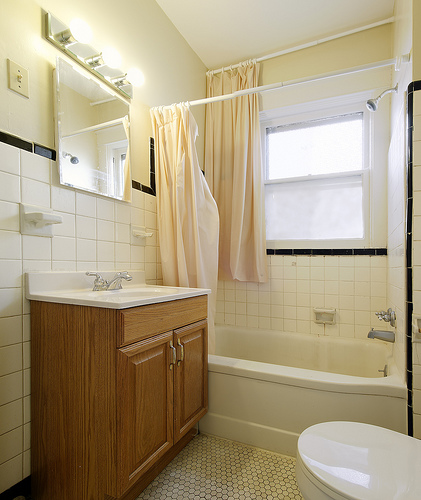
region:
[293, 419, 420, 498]
toilet with the seat and lid down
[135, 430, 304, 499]
hexagonal tile floor pattern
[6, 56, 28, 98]
light switch in the on position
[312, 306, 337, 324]
soap dish in the wall of the shower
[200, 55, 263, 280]
peach colored curtain on the higher rod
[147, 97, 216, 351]
peach shower curtain on the lower pole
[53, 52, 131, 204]
mirror reflecting the shower head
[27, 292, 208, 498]
brown cabinets made out of wood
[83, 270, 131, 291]
silver metal sink faucet with two handles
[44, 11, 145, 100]
three lights in a row above the mirror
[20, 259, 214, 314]
sink in a bathroom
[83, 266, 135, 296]
faucet on a sink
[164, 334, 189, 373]
handles on vanity doors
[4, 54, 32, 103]
electrical switch on a wall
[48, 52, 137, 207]
mirror in a bathroom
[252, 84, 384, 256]
window on a wall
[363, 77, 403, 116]
shower head in a bathroom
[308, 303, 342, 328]
soap dish in a shower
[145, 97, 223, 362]
shower curtain on a rod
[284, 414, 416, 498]
white toilet in a bathroom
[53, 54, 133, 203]
Wall mounted mirror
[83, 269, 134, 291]
Silver double handle faucet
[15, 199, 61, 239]
White soap dish on wall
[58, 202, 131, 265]
White tiles on wall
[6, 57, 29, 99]
Single white light switch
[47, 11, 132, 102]
Silver wall mouted light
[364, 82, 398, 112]
Silver shower head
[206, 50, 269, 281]
Peach window curtain with white rod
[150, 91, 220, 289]
Peach shower curtain with white rod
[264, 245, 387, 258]
Black tile boarder under window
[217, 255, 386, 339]
White tiles on bathroom wall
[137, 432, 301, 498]
Hexagonal small tiles on bathroom floor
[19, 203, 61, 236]
Soap holder among tiles on wall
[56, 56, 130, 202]
Medicine cabinet mirror in bathroom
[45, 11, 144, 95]
Three light-bulb strip with mirror back in bathroom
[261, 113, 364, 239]
Window in bathroom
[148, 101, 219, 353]
Peach color shower curtain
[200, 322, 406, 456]
White bathtub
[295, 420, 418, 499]
White toilet with seat down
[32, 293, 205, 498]
Oak cabinet in bathroom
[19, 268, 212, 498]
Wooden bathroom vanity.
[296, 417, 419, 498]
White toilet with the lid down.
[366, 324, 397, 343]
Bathtub faucet.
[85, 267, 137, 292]
Bathroom sink faucet.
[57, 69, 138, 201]
Bathroom vanity mirror.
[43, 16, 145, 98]
Bathroom lighting fixture.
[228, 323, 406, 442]
White porcelain bathtub with metal faucet.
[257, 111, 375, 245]
Rectangular window in a bathroom shower.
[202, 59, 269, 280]
Beige bathroom curtain pulled open.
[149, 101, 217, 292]
Opened beige shower curtain.